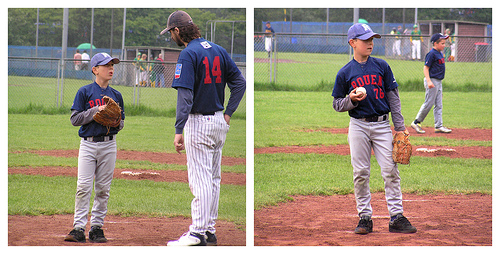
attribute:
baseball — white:
[355, 85, 366, 96]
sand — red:
[247, 181, 494, 251]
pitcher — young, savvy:
[334, 26, 414, 233]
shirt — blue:
[168, 43, 237, 115]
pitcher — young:
[63, 48, 132, 245]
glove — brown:
[91, 92, 119, 125]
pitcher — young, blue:
[328, 22, 430, 237]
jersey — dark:
[334, 58, 396, 119]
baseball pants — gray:
[75, 136, 115, 231]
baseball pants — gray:
[347, 115, 405, 220]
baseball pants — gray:
[182, 115, 228, 236]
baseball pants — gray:
[412, 76, 443, 123]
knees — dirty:
[74, 186, 111, 198]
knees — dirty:
[353, 168, 398, 187]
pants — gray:
[326, 115, 440, 227]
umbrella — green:
[74, 40, 97, 53]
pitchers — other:
[384, 21, 454, 56]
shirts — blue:
[326, 55, 404, 118]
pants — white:
[261, 36, 273, 56]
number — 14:
[199, 50, 225, 87]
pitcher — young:
[344, 111, 406, 223]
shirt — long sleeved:
[170, 69, 247, 138]